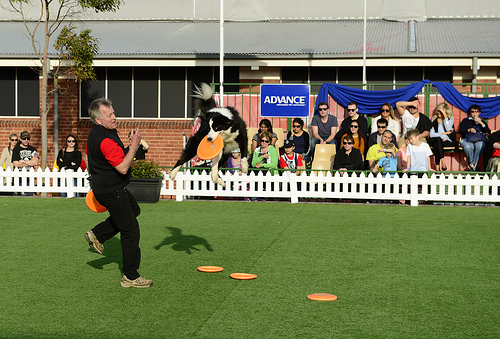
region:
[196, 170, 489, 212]
a small white picket fence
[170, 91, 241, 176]
a dog catching a frisbee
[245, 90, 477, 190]
several people sitting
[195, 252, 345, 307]
three orange firsbee's on the ground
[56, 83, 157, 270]
a man wearing a black vest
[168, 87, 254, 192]
a black and white dog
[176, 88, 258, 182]
a dog with a frisbee in its mouth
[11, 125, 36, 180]
a man with his arms crossed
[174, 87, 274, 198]
a dog jumping in the air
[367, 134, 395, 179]
a little boy wearing a blue shirt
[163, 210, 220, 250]
shadow on the lawn.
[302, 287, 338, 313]
disc on the grass.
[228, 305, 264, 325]
grass on the ground.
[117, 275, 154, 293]
shoe on man's foot.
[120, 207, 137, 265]
black pants on man's leg.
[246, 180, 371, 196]
white fence along the edge of field.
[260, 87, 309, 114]
white writing on blue sign.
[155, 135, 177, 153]
wall made of brick.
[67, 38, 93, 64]
green leaves on tree.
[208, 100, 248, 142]
dog in the air.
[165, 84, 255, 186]
A dog in the air.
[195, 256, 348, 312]
Orange frisbees on the ground.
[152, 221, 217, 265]
Shadow of a dog.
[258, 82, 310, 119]
A blue sign.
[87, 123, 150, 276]
a black vest and jeans.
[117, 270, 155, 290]
A dirty shoe.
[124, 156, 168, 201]
A planter with flowers.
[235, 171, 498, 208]
A white pickett fence.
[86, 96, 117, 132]
The man is balding.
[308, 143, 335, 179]
An empty seat chair.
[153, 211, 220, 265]
Dog is casting a shadow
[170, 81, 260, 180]
The dogs coat is black and white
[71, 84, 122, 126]
Man has gray hair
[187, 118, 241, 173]
Dog has a flying disc in its mouth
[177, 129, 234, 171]
Flying disc is orange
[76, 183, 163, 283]
Man is wearing black pants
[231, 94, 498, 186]
A crowd of people in the background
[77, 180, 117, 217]
Man is holding a flying disc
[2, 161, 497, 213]
A small white fence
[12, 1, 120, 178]
A tree is in the background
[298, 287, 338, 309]
frisbee on the ground.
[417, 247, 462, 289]
grass on the ground.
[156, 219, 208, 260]
shadow on the ground.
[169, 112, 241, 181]
dog in the air.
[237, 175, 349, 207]
white fence along the grass.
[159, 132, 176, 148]
brick wall of building.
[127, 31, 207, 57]
tin roof of building.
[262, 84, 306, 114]
white word on sign.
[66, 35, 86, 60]
leaves on the tree.